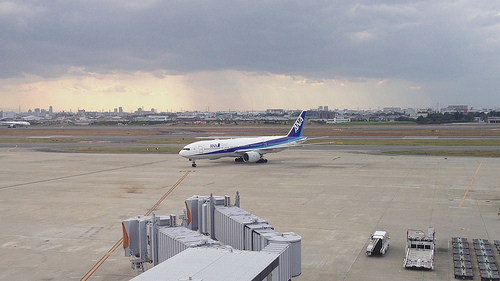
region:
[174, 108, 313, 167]
The jet is grounded.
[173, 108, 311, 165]
The jet is white and blue.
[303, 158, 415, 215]
The concrete is grey.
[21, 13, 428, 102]
The sky is cloudy.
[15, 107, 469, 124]
There is a city in the background.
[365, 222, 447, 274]
I see two luggage trucks.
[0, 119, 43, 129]
This plane is grounded as well.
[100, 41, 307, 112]
The sun is trying to come through.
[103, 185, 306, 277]
There is nobody boarding the plane.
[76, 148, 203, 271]
The strip is orange.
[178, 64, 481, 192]
a plane on the ground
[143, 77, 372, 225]
an airplane on the ground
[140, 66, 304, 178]
a passenger plane on the ground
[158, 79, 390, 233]
a passenger airplane on the ground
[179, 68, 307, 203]
a white plane on the road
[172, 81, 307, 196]
a white airplane on the ground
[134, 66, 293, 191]
a large plane on the ground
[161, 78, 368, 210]
a white passenger plane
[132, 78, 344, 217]
a white passenger airplane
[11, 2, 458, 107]
It's a cloudy day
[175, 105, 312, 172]
Airline is ANA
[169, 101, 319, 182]
Airplane is taxiing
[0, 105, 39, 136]
The airplane is on a runway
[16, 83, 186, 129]
There are tall buildings in the background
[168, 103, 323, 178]
This is a commercial plane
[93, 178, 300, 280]
There are two jettys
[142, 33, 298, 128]
It is raining in the background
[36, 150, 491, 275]
There are lines drawn on the ground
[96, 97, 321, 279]
The airplane is at the airport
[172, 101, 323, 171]
plane on the runway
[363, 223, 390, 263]
vehicle on the runway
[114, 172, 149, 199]
spot on the ground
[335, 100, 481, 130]
city in the background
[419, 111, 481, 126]
bushes across the runway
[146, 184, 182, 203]
orange line on the ground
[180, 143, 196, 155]
windows on the plane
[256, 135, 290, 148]
blue on the plane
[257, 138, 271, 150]
door on the plane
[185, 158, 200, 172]
wheel on front of the plane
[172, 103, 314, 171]
An commercial airplane stationed at an airport